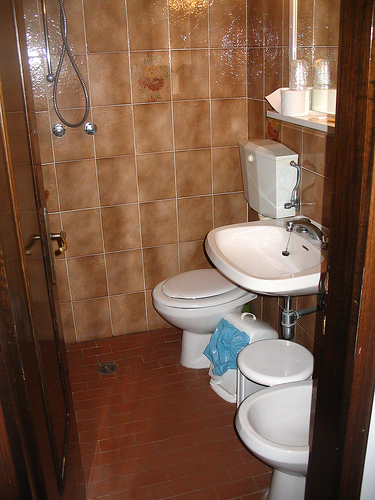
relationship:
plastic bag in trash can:
[202, 319, 250, 378] [207, 312, 278, 405]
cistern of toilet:
[237, 136, 301, 218] [153, 135, 302, 371]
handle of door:
[46, 217, 76, 270] [6, 109, 96, 490]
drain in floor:
[92, 358, 124, 378] [70, 339, 272, 499]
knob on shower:
[52, 124, 66, 140] [23, 0, 245, 465]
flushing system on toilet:
[237, 137, 299, 217] [148, 135, 301, 404]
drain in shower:
[92, 358, 124, 378] [27, 7, 253, 362]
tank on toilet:
[236, 141, 298, 212] [135, 246, 261, 359]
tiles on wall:
[75, 167, 143, 249] [29, 15, 306, 433]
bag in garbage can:
[203, 320, 249, 382] [208, 310, 276, 406]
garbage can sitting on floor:
[208, 310, 279, 398] [65, 320, 294, 498]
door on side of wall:
[8, 124, 32, 425] [115, 34, 202, 170]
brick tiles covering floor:
[93, 364, 188, 465] [89, 370, 203, 494]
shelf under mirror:
[263, 98, 333, 137] [281, 2, 335, 115]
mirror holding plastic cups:
[281, 2, 335, 115] [285, 56, 312, 94]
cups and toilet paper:
[285, 56, 312, 94] [265, 81, 311, 118]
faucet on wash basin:
[282, 217, 332, 262] [211, 212, 330, 311]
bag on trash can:
[203, 320, 249, 382] [214, 313, 278, 396]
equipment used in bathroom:
[240, 339, 313, 380] [2, 2, 374, 492]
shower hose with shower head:
[37, 8, 104, 131] [46, 69, 58, 83]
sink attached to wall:
[205, 207, 323, 307] [86, 31, 230, 129]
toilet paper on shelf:
[275, 80, 307, 115] [263, 98, 333, 137]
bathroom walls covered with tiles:
[7, 2, 324, 341] [24, 2, 247, 224]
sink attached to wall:
[205, 207, 323, 307] [249, 6, 340, 363]